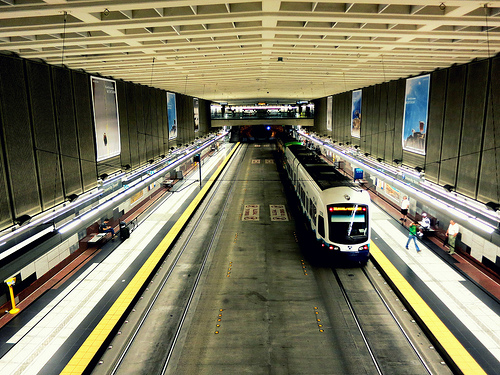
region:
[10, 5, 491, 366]
overhead view of a train station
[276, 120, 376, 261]
train in the station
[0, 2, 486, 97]
architectural element up above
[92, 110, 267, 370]
train tracks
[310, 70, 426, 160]
posters on the wall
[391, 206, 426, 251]
people on the platform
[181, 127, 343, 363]
asphalt track area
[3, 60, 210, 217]
black side panels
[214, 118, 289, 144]
tunnel for trains to go through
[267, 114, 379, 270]
the train on the track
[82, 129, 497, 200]
power lines above the train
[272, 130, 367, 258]
the train at the station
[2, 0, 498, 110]
the roof of the station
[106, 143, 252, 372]
the adjacent tracks are empty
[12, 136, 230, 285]
the lights hanging from the roof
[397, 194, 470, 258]
people at the station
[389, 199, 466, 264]
the people are waiting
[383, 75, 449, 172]
the ad on the wall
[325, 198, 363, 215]
the led display on the train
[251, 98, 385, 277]
this is a train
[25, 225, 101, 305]
this is a railway line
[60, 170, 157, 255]
this is a railway line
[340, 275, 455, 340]
this is a railway line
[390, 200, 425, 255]
this is a person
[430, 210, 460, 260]
this is a person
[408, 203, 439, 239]
this is a person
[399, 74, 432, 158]
Poster on wall of train station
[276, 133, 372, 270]
Train sitting on track in train station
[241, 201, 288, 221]
Sign painted on road near train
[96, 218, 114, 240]
Person sitting on bench in train station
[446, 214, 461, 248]
Man in white shirt standing in train station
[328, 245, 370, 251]
Red lights on front of train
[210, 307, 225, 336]
Yellow markers in road near train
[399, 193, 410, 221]
Man in black shorts standing near train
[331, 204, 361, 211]
Digital sign on top of train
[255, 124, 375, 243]
white top on train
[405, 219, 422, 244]
person wearing green shirt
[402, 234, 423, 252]
person wearing blue pants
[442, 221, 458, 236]
person wearing white shirt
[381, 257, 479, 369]
yellow trim on platform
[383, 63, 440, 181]
blue sign on wall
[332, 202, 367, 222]
orange sign on train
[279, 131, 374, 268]
white passenger train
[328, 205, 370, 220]
orange destination sign on train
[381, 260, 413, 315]
yellow caution stripe on platform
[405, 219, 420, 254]
person wearing green shirt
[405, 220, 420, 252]
person walking beside train tracks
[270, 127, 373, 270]
long white train with black roof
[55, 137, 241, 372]
yellow line denoting side of railroad track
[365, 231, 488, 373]
yellow line denoting side of railroad track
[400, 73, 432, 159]
large poster hanging on wall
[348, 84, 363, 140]
large poster hanging on wall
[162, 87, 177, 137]
large poster hanging on wall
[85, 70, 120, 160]
large poster hanging on wall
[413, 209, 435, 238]
person with white shirt sitting on bench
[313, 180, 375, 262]
a train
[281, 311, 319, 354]
the ground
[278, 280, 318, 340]
the ground is grey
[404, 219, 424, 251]
a person walking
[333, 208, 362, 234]
a windshield of the train